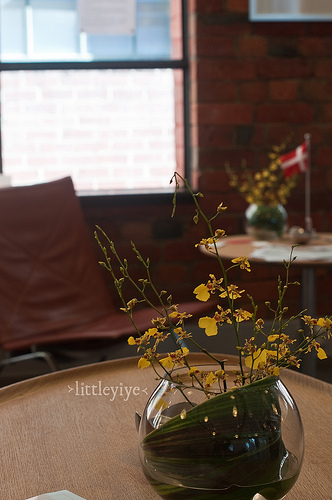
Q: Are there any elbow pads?
A: No, there are no elbow pads.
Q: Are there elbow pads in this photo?
A: No, there are no elbow pads.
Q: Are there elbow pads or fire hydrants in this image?
A: No, there are no elbow pads or fire hydrants.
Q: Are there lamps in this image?
A: No, there are no lamps.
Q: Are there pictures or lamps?
A: No, there are no lamps or pictures.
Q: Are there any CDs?
A: No, there are no cds.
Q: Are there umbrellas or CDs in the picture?
A: No, there are no CDs or umbrellas.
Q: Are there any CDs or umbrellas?
A: No, there are no CDs or umbrellas.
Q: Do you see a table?
A: Yes, there is a table.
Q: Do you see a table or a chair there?
A: Yes, there is a table.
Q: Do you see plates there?
A: No, there are no plates.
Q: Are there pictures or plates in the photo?
A: No, there are no plates or pictures.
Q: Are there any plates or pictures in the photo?
A: No, there are no plates or pictures.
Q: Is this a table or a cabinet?
A: This is a table.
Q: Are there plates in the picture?
A: No, there are no plates.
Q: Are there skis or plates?
A: No, there are no plates or skis.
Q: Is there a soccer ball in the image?
A: No, there are no soccer balls.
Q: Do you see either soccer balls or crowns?
A: No, there are no soccer balls or crowns.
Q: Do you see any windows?
A: Yes, there is a window.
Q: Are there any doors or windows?
A: Yes, there is a window.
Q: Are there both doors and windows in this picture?
A: No, there is a window but no doors.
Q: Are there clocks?
A: No, there are no clocks.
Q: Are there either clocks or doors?
A: No, there are no clocks or doors.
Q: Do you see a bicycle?
A: No, there are no bicycles.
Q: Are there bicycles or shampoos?
A: No, there are no bicycles or shampoos.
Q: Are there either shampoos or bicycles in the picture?
A: No, there are no bicycles or shampoos.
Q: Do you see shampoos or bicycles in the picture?
A: No, there are no bicycles or shampoos.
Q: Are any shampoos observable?
A: No, there are no shampoos.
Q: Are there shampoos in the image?
A: No, there are no shampoos.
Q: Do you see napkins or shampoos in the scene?
A: No, there are no shampoos or napkins.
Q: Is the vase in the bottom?
A: Yes, the vase is in the bottom of the image.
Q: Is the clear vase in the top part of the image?
A: No, the vase is in the bottom of the image.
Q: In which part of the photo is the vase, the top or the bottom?
A: The vase is in the bottom of the image.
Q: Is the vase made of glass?
A: Yes, the vase is made of glass.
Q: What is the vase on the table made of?
A: The vase is made of glass.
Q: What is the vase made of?
A: The vase is made of glass.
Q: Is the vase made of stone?
A: No, the vase is made of glass.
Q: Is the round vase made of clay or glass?
A: The vase is made of glass.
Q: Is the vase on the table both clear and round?
A: Yes, the vase is clear and round.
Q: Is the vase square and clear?
A: No, the vase is clear but round.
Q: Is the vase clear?
A: Yes, the vase is clear.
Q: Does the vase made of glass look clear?
A: Yes, the vase is clear.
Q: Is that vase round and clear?
A: Yes, the vase is round and clear.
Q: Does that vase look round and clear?
A: Yes, the vase is round and clear.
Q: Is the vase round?
A: Yes, the vase is round.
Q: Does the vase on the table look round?
A: Yes, the vase is round.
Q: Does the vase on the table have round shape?
A: Yes, the vase is round.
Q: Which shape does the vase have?
A: The vase has round shape.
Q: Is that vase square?
A: No, the vase is round.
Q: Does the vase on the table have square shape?
A: No, the vase is round.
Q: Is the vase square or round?
A: The vase is round.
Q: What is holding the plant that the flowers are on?
A: The vase is holding the plant.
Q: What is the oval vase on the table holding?
A: The vase is holding the plant.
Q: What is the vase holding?
A: The vase is holding the plant.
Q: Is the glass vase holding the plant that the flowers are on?
A: Yes, the vase is holding the plant.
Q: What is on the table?
A: The vase is on the table.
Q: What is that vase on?
A: The vase is on the table.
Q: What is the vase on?
A: The vase is on the table.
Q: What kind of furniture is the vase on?
A: The vase is on the table.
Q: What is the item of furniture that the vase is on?
A: The piece of furniture is a table.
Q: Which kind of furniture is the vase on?
A: The vase is on the table.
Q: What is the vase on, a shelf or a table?
A: The vase is on a table.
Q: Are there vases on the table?
A: Yes, there is a vase on the table.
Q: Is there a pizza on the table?
A: No, there is a vase on the table.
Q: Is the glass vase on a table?
A: Yes, the vase is on a table.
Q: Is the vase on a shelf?
A: No, the vase is on a table.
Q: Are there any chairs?
A: Yes, there is a chair.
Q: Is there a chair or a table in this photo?
A: Yes, there is a chair.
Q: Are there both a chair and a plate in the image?
A: No, there is a chair but no plates.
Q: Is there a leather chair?
A: Yes, there is a chair that is made of leather.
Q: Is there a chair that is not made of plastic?
A: Yes, there is a chair that is made of leather.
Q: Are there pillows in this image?
A: No, there are no pillows.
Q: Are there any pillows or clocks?
A: No, there are no pillows or clocks.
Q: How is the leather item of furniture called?
A: The piece of furniture is a chair.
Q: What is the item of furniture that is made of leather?
A: The piece of furniture is a chair.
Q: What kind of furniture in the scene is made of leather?
A: The furniture is a chair.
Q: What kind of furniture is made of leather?
A: The furniture is a chair.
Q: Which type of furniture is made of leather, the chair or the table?
A: The chair is made of leather.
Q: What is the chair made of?
A: The chair is made of leather.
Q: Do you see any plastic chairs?
A: No, there is a chair but it is made of leather.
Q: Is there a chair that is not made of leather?
A: No, there is a chair but it is made of leather.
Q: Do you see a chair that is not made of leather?
A: No, there is a chair but it is made of leather.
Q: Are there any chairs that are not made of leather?
A: No, there is a chair but it is made of leather.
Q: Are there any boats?
A: No, there are no boats.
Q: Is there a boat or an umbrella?
A: No, there are no boats or umbrellas.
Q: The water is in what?
A: The water is in the vase.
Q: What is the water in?
A: The water is in the vase.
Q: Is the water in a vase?
A: Yes, the water is in a vase.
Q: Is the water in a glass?
A: No, the water is in a vase.